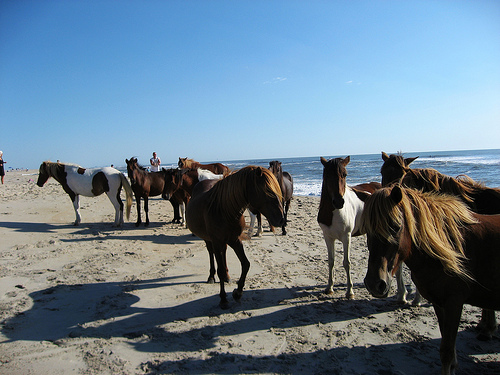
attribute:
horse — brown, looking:
[182, 157, 296, 306]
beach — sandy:
[6, 164, 499, 369]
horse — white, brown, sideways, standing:
[33, 151, 136, 231]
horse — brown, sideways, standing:
[125, 154, 192, 221]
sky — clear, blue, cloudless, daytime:
[0, 0, 499, 174]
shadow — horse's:
[2, 268, 206, 339]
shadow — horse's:
[83, 268, 369, 347]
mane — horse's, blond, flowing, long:
[358, 183, 480, 281]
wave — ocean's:
[421, 149, 497, 168]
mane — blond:
[202, 160, 283, 222]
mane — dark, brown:
[128, 159, 150, 174]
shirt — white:
[150, 156, 162, 171]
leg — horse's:
[229, 240, 254, 301]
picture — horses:
[8, 0, 499, 364]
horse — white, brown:
[311, 150, 401, 301]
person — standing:
[147, 148, 163, 174]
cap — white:
[414, 149, 498, 164]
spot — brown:
[91, 171, 110, 196]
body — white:
[58, 165, 126, 224]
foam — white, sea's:
[290, 174, 325, 199]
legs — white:
[320, 228, 358, 304]